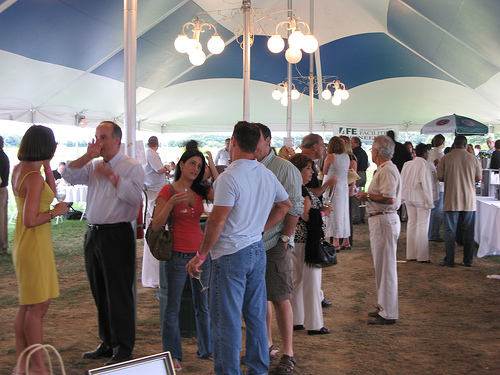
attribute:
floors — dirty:
[13, 231, 497, 374]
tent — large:
[6, 8, 483, 128]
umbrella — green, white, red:
[420, 112, 487, 134]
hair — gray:
[373, 130, 398, 162]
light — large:
[263, 35, 292, 57]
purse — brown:
[138, 219, 183, 258]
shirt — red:
[154, 185, 205, 251]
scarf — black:
[307, 207, 324, 264]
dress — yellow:
[9, 163, 66, 308]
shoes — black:
[75, 326, 170, 370]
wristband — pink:
[194, 253, 204, 263]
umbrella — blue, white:
[4, 2, 499, 157]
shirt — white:
[55, 152, 144, 223]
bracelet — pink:
[193, 250, 207, 264]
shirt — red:
[186, 145, 305, 262]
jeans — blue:
[202, 243, 274, 373]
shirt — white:
[205, 159, 291, 266]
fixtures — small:
[174, 11, 350, 106]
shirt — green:
[261, 154, 303, 246]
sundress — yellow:
[12, 171, 60, 302]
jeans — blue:
[208, 242, 271, 372]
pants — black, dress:
[84, 222, 136, 345]